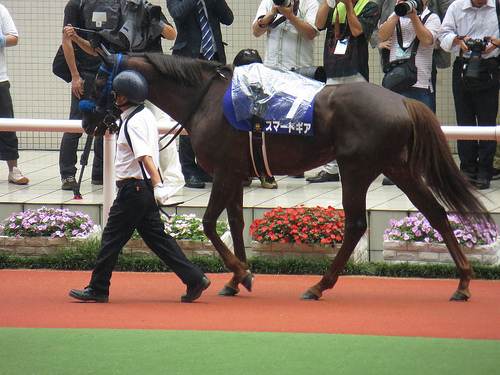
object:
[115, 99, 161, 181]
shirt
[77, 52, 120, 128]
harness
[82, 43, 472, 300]
horse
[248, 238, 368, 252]
planter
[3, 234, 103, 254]
planter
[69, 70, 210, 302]
man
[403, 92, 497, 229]
horse's tail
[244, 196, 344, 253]
red flowers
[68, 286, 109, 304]
man's left foot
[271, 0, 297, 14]
camera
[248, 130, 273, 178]
horse's belly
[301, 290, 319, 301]
horse's hoof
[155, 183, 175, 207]
white glove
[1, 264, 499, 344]
ground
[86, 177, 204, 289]
man wearing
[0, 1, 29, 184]
people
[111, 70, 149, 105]
head gear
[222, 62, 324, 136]
blue saddle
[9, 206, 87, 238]
pink flowers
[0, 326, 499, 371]
green floor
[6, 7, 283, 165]
white brick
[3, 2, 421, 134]
white bridk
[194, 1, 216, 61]
blue tie